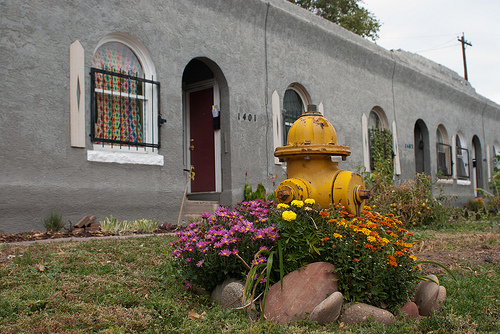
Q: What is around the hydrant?
A: Flowers.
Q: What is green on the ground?
A: Grass.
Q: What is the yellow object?
A: Fire hydrant.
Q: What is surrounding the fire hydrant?
A: Flowers.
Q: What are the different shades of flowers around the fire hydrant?
A: Purple, yellow and orange.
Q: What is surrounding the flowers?
A: Rocks.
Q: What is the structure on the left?
A: Grey stone building.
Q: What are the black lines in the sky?
A: Power lines.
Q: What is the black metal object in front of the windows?
A: Security rails.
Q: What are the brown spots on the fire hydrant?
A: Rust.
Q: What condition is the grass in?
A: Green and yellowed.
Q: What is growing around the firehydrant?
A: Flowers.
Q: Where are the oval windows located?
A: House.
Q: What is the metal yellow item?
A: Fire hydrant.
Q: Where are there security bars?
A: Across windows.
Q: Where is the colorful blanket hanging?
A: Inside window.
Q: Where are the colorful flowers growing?
A: Around fire hydrant.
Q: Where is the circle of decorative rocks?
A: Around flowers.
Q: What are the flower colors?
A: Pink, yellow and orange.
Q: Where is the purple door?
A: House.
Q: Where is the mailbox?
A: By purple door.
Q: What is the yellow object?
A: Fire hydrant.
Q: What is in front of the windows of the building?
A: Black metal grate.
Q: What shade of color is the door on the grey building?
A: Maroon.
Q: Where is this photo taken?
A: Apartment building.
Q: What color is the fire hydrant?
A: Yellow.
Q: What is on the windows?
A: Bars.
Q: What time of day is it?
A: Daytime.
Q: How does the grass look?
A: Sparse.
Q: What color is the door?
A: Red.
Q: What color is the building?
A: Gray.